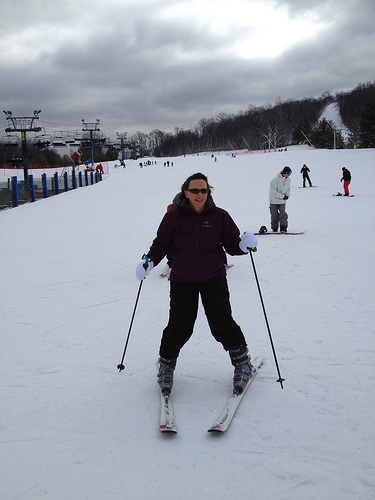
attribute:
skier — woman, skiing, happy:
[134, 173, 260, 396]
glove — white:
[237, 231, 258, 254]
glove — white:
[136, 254, 154, 281]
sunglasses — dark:
[185, 186, 210, 196]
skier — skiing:
[267, 166, 291, 232]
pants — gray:
[267, 203, 289, 232]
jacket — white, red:
[268, 173, 290, 207]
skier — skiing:
[339, 167, 352, 195]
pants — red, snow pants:
[341, 181, 350, 196]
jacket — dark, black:
[341, 169, 351, 180]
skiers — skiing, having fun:
[139, 159, 175, 169]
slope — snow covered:
[2, 147, 374, 499]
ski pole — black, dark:
[117, 254, 154, 374]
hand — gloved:
[137, 258, 155, 281]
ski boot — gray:
[158, 355, 178, 395]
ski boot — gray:
[229, 346, 255, 395]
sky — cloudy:
[2, 2, 373, 153]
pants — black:
[159, 277, 246, 361]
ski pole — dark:
[243, 230, 285, 388]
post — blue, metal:
[12, 175, 20, 208]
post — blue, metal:
[28, 173, 37, 202]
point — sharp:
[279, 381, 286, 391]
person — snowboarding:
[300, 164, 314, 188]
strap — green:
[142, 253, 149, 265]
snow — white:
[313, 101, 353, 141]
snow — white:
[0, 142, 374, 500]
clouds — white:
[162, 0, 340, 66]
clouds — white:
[4, 23, 92, 59]